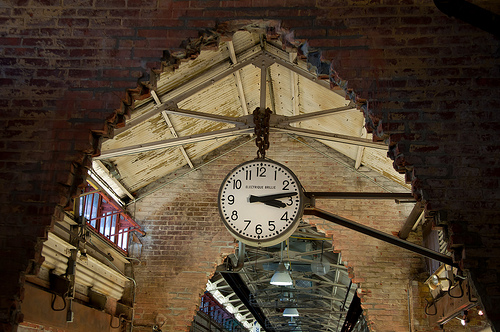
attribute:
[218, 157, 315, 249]
clock — round, displaying time, large, circular, 3:14, hung up, white, big, central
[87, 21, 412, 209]
ceiling — old, wooden, slanted, brown, wood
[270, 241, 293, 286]
ceiling light — hanging, on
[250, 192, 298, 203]
hand — metallic, black, long, 3:13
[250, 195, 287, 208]
hand — metallic, black, short, 3:13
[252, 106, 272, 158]
chain — metal, heavy, rusty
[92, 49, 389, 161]
beam — metal, overhead, white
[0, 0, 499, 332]
wall — brick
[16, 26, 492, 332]
entrance — open, arched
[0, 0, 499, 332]
building — red, brick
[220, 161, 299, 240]
face — white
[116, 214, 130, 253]
window — shining, metal, orange, red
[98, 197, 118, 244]
window — shining, metal, orange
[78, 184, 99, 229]
window — shining, metal, orange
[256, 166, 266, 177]
number — black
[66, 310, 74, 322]
electrical box — small, gray